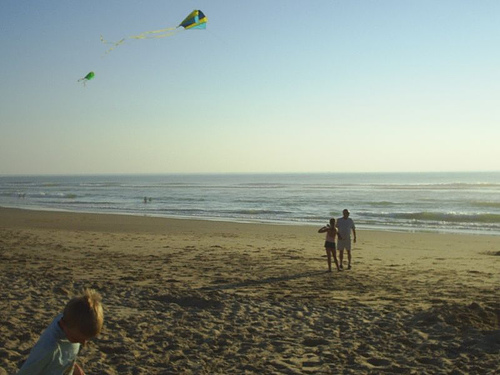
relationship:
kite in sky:
[102, 7, 209, 62] [20, 24, 489, 158]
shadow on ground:
[157, 244, 337, 297] [103, 267, 485, 362]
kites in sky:
[72, 8, 209, 89] [12, 10, 495, 168]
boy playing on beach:
[36, 266, 130, 373] [93, 215, 273, 320]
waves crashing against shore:
[0, 175, 499, 237] [0, 206, 499, 373]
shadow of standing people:
[151, 261, 333, 311] [338, 204, 359, 269]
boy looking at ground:
[22, 288, 104, 375] [1, 205, 499, 374]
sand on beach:
[196, 237, 267, 268] [18, 186, 450, 371]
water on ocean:
[5, 173, 480, 233] [5, 170, 492, 248]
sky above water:
[0, 0, 472, 161] [276, 160, 484, 200]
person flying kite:
[313, 216, 343, 269] [99, 2, 279, 54]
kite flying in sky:
[58, 7, 218, 94] [4, 2, 494, 234]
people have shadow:
[316, 206, 358, 274] [149, 271, 335, 309]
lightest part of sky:
[431, 144, 481, 172] [3, 5, 499, 189]